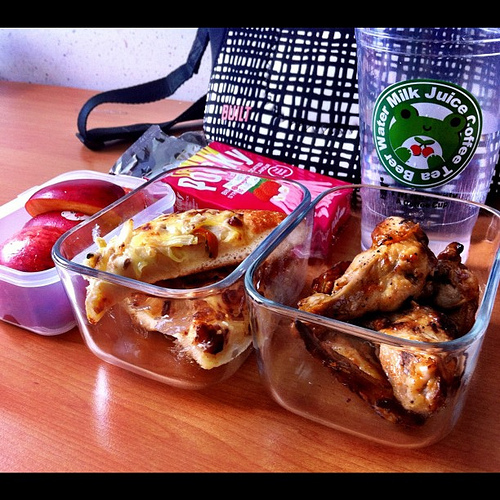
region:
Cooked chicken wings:
[296, 213, 468, 409]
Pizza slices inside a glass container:
[86, 205, 248, 360]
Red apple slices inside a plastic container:
[1, 177, 139, 269]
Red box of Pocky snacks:
[170, 142, 353, 207]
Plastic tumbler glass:
[355, 32, 497, 250]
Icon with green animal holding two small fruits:
[392, 102, 464, 169]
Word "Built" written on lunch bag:
[215, 103, 255, 124]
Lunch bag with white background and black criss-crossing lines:
[201, 25, 359, 160]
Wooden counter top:
[4, 376, 301, 471]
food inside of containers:
[27, 152, 476, 436]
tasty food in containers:
[16, 180, 491, 439]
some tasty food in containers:
[22, 177, 481, 450]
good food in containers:
[15, 175, 476, 446]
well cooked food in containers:
[16, 181, 476, 454]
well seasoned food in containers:
[20, 179, 485, 461]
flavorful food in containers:
[60, 174, 493, 456]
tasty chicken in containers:
[270, 192, 482, 461]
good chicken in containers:
[285, 196, 476, 450]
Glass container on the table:
[246, 182, 496, 447]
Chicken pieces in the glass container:
[295, 213, 477, 418]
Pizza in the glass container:
[82, 206, 303, 371]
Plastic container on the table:
[0, 167, 177, 337]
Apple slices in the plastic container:
[1, 174, 161, 273]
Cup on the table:
[356, 27, 498, 263]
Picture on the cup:
[373, 81, 482, 189]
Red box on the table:
[111, 124, 354, 259]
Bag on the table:
[201, 30, 496, 235]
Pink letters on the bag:
[220, 100, 251, 122]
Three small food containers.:
[0, 163, 499, 448]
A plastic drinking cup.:
[354, 27, 499, 261]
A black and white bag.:
[77, 28, 498, 208]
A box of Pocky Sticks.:
[107, 124, 351, 257]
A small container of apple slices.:
[0, 169, 176, 335]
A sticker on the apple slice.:
[21, 210, 109, 243]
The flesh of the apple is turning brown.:
[25, 180, 122, 223]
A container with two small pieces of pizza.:
[54, 163, 311, 387]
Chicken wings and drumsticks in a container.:
[297, 215, 479, 429]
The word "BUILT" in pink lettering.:
[216, 103, 254, 123]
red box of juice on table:
[113, 116, 396, 261]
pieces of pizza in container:
[73, 191, 310, 379]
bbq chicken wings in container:
[261, 198, 498, 439]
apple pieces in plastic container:
[0, 153, 184, 343]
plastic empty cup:
[319, 18, 499, 267]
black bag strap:
[65, 20, 276, 159]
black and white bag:
[196, 17, 496, 232]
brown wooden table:
[2, 83, 486, 477]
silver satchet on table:
[87, 120, 237, 190]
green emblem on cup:
[368, 62, 498, 198]